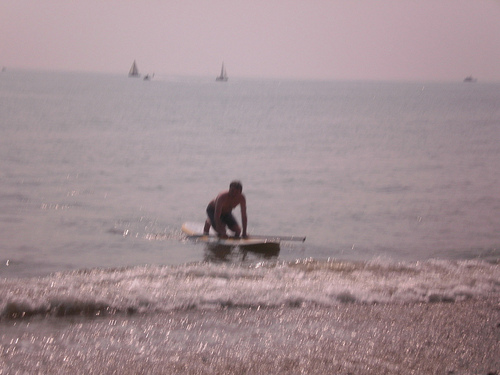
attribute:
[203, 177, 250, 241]
man — shirtless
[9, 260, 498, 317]
wave — small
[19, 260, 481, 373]
wave — small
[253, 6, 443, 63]
cloudy — gray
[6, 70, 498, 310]
ocean — sparkling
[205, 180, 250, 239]
man — kneeling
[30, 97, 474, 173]
water — calm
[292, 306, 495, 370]
shore — wet, sandy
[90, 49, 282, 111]
boats — small